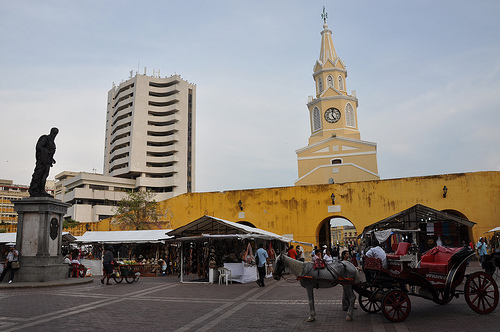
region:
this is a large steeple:
[297, 6, 426, 198]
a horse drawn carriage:
[267, 238, 497, 326]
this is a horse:
[260, 233, 385, 328]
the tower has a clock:
[295, 5, 410, 175]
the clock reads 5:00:
[315, 100, 351, 126]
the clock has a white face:
[316, 97, 348, 127]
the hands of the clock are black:
[325, 99, 344, 127]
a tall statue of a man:
[17, 88, 94, 280]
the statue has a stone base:
[5, 193, 100, 299]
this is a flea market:
[91, 213, 281, 299]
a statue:
[28, 123, 67, 284]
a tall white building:
[113, 63, 199, 185]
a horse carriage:
[277, 211, 496, 322]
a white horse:
[272, 247, 364, 320]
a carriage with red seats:
[363, 229, 499, 319]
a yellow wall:
[80, 183, 490, 254]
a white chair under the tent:
[217, 263, 232, 279]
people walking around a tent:
[246, 226, 373, 272]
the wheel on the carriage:
[467, 270, 492, 305]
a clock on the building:
[325, 103, 347, 122]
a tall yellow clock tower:
[290, 5, 383, 180]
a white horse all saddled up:
[271, 255, 361, 323]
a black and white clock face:
[325, 105, 344, 122]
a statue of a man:
[28, 125, 60, 197]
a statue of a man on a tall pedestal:
[13, 127, 66, 284]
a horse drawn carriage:
[266, 223, 496, 325]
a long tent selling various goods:
[77, 213, 291, 277]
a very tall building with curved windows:
[60, 63, 195, 220]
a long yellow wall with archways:
[59, 170, 497, 266]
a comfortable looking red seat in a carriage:
[364, 243, 462, 280]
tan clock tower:
[294, 21, 363, 183]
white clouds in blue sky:
[380, 51, 417, 95]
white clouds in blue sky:
[408, 37, 483, 76]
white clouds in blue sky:
[210, 10, 276, 58]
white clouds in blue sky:
[208, 71, 261, 129]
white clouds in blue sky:
[401, 46, 468, 101]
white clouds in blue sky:
[24, 17, 75, 56]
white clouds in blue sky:
[219, 42, 267, 104]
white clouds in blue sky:
[369, 49, 445, 100]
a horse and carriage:
[272, 243, 494, 320]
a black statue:
[29, 126, 64, 197]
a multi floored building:
[104, 72, 202, 191]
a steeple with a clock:
[295, 17, 381, 185]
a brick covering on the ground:
[82, 293, 258, 324]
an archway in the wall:
[311, 212, 366, 267]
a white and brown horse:
[269, 250, 378, 321]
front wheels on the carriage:
[357, 281, 412, 327]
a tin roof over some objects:
[169, 214, 299, 246]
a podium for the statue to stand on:
[8, 194, 72, 286]